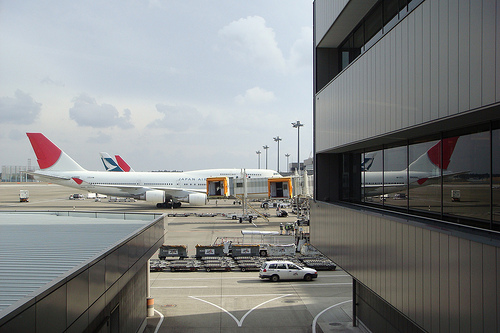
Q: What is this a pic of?
A: Airport.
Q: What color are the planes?
A: White.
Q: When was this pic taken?
A: During the daytime.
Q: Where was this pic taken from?
A: Inside the airport.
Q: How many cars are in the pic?
A: 1.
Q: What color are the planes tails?
A: Red.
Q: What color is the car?
A: White.